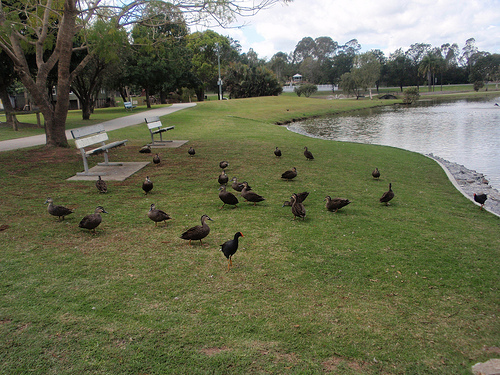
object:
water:
[279, 81, 500, 219]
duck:
[219, 231, 245, 271]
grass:
[0, 90, 500, 374]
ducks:
[42, 199, 74, 223]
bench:
[144, 116, 174, 146]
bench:
[70, 123, 128, 176]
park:
[1, 0, 500, 375]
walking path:
[0, 102, 197, 151]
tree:
[0, 0, 294, 146]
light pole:
[215, 47, 224, 100]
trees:
[456, 51, 499, 91]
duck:
[281, 167, 297, 184]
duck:
[323, 195, 352, 213]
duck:
[188, 146, 196, 159]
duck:
[142, 175, 153, 196]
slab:
[140, 140, 189, 149]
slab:
[63, 161, 153, 182]